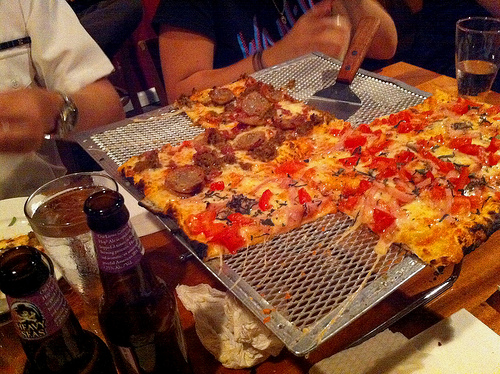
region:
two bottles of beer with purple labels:
[9, 187, 187, 370]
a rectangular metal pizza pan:
[74, 47, 436, 359]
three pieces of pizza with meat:
[121, 67, 341, 212]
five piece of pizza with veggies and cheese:
[180, 94, 497, 269]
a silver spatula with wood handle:
[302, 17, 385, 119]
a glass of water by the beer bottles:
[21, 168, 120, 315]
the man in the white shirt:
[0, 1, 121, 188]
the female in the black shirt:
[158, 2, 398, 102]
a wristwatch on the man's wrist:
[50, 89, 77, 140]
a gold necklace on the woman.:
[274, 1, 287, 23]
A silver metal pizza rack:
[68, 48, 497, 355]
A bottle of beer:
[82, 188, 192, 372]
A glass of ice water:
[22, 168, 118, 340]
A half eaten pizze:
[117, 70, 497, 272]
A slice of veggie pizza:
[338, 150, 498, 272]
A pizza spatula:
[305, 14, 380, 121]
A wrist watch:
[43, 89, 78, 143]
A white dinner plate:
[1, 193, 91, 317]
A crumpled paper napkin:
[174, 283, 286, 370]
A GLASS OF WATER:
[452, 12, 498, 107]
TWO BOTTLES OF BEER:
[1, 185, 193, 370]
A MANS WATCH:
[45, 84, 83, 146]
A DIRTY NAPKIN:
[171, 281, 286, 372]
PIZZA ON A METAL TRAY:
[68, 49, 498, 362]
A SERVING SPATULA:
[298, 12, 386, 122]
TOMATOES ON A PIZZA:
[176, 205, 258, 255]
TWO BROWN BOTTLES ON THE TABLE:
[1, 182, 194, 367]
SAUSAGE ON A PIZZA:
[156, 125, 301, 200]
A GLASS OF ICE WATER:
[20, 166, 127, 339]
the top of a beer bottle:
[2, 243, 92, 367]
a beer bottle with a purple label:
[80, 185, 180, 362]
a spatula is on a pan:
[310, 19, 382, 116]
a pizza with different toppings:
[125, 78, 498, 262]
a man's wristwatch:
[51, 89, 82, 141]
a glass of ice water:
[23, 170, 93, 275]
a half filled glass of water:
[454, 14, 499, 102]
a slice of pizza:
[122, 128, 229, 201]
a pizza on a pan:
[133, 59, 491, 270]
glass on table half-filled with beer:
[447, 16, 498, 101]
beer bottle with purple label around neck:
[82, 181, 163, 370]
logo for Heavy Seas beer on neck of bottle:
[7, 259, 86, 364]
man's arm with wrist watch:
[39, 82, 89, 145]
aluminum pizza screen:
[214, 212, 396, 342]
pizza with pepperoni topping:
[186, 98, 336, 168]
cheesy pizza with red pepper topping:
[340, 128, 472, 215]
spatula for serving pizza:
[309, 5, 384, 119]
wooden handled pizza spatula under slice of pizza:
[302, 15, 384, 126]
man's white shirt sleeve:
[6, 0, 122, 105]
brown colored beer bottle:
[2, 238, 89, 361]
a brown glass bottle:
[85, 192, 191, 368]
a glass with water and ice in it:
[26, 170, 104, 287]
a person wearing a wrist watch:
[52, 85, 82, 138]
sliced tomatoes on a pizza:
[180, 199, 249, 254]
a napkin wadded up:
[177, 278, 287, 372]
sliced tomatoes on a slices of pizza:
[347, 135, 479, 197]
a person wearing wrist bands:
[242, 49, 282, 76]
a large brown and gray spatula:
[303, 13, 383, 124]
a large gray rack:
[76, 50, 432, 361]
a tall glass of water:
[22, 168, 138, 324]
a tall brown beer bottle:
[81, 191, 191, 372]